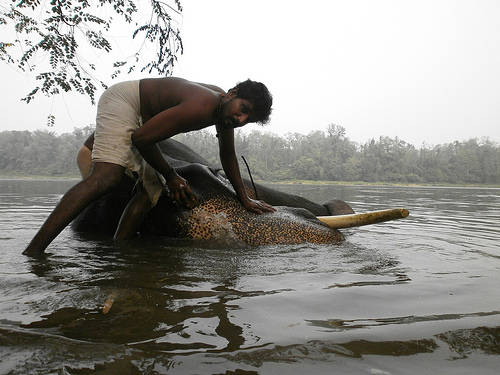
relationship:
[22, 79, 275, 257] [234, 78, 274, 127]
man has hair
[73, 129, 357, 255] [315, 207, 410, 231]
elephant has a tusk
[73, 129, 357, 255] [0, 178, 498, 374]
elephant in water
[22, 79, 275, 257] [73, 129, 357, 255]
man touching elephant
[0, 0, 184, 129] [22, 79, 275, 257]
branches over man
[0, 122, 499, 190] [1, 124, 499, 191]
trees in distance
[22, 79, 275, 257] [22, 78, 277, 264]
man has dark skin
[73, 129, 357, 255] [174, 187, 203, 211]
elephant getting a bath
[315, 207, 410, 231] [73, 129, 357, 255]
tusk on elephant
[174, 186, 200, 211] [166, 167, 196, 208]
sponge in mans hand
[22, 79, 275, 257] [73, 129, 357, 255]
man bathing elephant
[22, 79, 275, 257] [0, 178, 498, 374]
man in water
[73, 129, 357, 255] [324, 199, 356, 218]
elephant has a foot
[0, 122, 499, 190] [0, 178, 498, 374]
trees along water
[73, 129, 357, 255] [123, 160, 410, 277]
elephant has a head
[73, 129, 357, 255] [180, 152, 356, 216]
elephant has a leg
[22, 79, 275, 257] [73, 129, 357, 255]
man handling elephant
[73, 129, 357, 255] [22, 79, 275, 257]
elephant getting a bath from man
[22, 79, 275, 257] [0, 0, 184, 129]
man under branches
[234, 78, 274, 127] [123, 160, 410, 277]
hair on top of mans head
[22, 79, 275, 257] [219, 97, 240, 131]
man has a beard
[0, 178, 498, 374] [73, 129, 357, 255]
water around elephant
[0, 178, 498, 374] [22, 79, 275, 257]
water around man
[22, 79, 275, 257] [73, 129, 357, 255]
man washing elephant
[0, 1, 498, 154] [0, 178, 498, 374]
sky above water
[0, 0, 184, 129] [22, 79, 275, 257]
branches above man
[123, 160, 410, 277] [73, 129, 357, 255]
head of elephant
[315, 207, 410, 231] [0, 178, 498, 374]
tusk sticking out of water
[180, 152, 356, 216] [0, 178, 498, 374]
leg sticking out of water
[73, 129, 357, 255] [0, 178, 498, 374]
elephant in shallow water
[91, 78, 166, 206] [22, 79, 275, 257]
cloth wrapped around man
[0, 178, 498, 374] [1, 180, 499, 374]
water color of brown